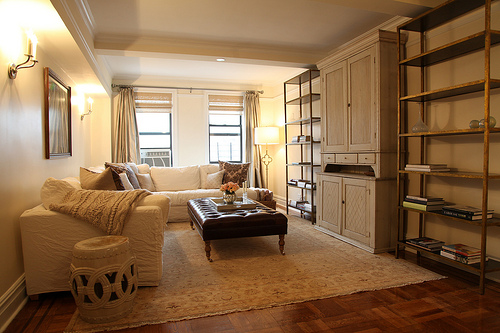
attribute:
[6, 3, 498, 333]
living room — beige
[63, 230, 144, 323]
basket style table — here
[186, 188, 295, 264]
coffee table — brown, here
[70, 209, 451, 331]
carpet — beige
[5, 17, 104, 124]
sconce lights — on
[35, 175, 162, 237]
blanket — beige, tan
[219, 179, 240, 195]
flowers — pink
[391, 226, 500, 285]
bottom shelf — brown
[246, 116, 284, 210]
floor lamp — on, tall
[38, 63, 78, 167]
art — framed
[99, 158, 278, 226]
couch — white, here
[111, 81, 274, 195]
curtains — open, here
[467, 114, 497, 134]
vase — glass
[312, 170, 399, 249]
cabinet — here, closed, wooden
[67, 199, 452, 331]
rug — here, tan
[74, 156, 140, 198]
pillows — here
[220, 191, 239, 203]
vase — tan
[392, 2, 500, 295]
bookshelf — here, tall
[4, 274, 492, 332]
floor — wooden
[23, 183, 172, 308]
chair — here